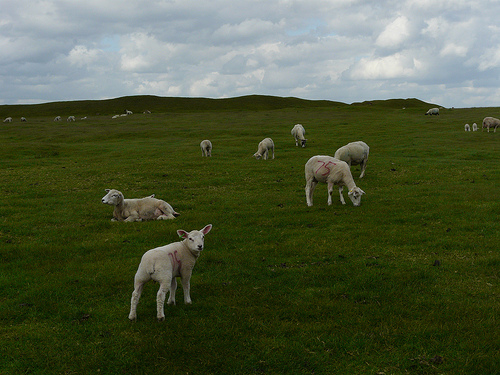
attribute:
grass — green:
[349, 250, 433, 301]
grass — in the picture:
[306, 266, 495, 366]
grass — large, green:
[2, 102, 498, 372]